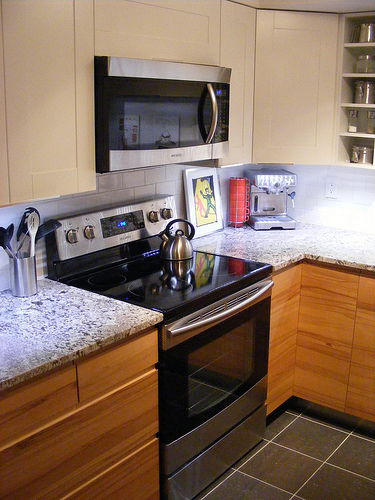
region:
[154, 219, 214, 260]
a silvery kettle on a stove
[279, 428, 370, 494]
clean linoleum in the kitchen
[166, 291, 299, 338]
a silvery stove handle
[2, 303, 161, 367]
a marble kitchen countertop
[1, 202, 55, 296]
a bunch of kitchen utensils in a pot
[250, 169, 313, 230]
a silvery espresso machine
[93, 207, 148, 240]
digital display on a stove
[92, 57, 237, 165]
a silver and black microwave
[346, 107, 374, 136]
salt and pepper shaker on a shelf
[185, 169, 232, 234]
a framed picture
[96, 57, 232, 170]
black and silver microwave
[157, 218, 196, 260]
silver teapot with black handle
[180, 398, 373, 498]
black tile floor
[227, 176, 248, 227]
stack of red cups on counter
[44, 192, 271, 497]
black and silver stove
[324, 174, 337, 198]
electrical outlet on wall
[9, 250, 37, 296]
silver can that holds utensils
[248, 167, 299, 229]
silver espresso machine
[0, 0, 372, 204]
white cabinets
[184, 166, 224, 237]
picture in silver frame leaning against wall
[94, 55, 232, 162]
silver and black microwave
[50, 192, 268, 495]
silver and black oven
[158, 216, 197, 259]
silver and black kettle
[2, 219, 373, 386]
white and black granite countertops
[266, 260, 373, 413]
brown wood cabinets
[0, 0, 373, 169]
white cabinets on top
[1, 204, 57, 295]
black and white cooking utensils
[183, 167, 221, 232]
picture with man standing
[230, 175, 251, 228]
orange coffee mug rack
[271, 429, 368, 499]
Gray tiled floor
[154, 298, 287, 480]
Black and stainless steal oven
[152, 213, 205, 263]
Silver teapot on a stove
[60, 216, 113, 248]
Knobs on a stove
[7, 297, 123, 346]
Marble counter by a stove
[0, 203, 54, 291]
Cup of cooking utensils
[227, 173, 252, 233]
Orange cups by a coffee maker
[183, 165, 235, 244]
Picture by a stove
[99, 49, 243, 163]
Microwave above a stove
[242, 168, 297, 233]
Esspresso maker on a counter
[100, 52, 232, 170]
Kitchen over the range microwave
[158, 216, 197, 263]
Silver metal tea kettle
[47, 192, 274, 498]
Black and metallic range unit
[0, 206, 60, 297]
Round metal cooking utensil holder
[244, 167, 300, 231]
Silver metal coffee maker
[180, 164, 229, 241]
Colorful painting leaning against wall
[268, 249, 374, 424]
Brown wooden kitchen cabinets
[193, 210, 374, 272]
Granite kitchen counter tops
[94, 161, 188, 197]
White tiled back splash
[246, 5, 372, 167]
Light brown kitchen cabinets